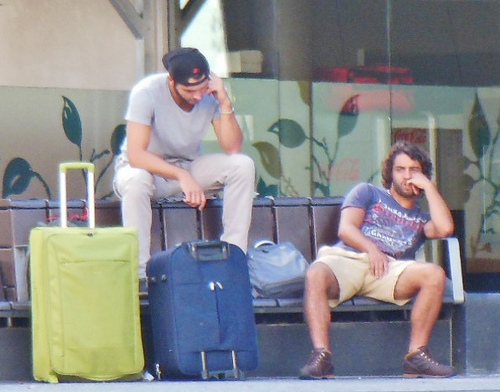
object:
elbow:
[125, 145, 149, 168]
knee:
[117, 162, 155, 199]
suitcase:
[145, 238, 258, 379]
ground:
[0, 377, 500, 392]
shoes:
[297, 345, 457, 380]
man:
[111, 47, 256, 291]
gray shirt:
[113, 71, 222, 199]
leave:
[61, 93, 86, 148]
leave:
[0, 156, 41, 201]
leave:
[265, 117, 305, 148]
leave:
[110, 121, 125, 153]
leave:
[252, 142, 280, 179]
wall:
[0, 0, 499, 259]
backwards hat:
[158, 46, 211, 88]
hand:
[404, 169, 434, 195]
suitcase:
[27, 160, 144, 384]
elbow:
[429, 205, 453, 238]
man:
[299, 140, 458, 380]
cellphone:
[207, 70, 214, 80]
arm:
[424, 200, 454, 240]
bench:
[0, 196, 467, 377]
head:
[380, 140, 431, 199]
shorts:
[313, 244, 416, 307]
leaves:
[336, 94, 357, 138]